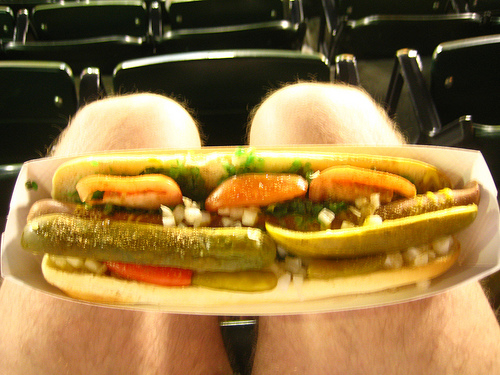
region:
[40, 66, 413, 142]
hairy, pale knees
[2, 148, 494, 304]
hot dog with toppings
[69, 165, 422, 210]
small sliced yellow peppers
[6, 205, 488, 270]
two green pickles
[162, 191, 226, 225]
chopped onion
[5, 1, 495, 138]
black stadium chairs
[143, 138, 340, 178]
green vegetable hot dog topping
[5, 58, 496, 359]
elaborate hot dog resting on a person's legs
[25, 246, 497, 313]
half hot dog bun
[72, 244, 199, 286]
grilled red pepper chunk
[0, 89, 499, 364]
A man has food resting on his legs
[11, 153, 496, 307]
A delicious snack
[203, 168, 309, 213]
A slice of tomato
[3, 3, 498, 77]
Green chairs set up in stadium seating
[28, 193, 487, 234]
A foot long hotdog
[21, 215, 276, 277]
A slice of pickle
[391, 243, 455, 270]
pieces of onion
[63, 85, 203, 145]
The kneecap of a white man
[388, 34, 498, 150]
A green chair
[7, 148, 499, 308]
A hotdog with a lot of trimmings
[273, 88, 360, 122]
Hairy Knee cap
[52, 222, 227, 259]
Pickle slice on hot dog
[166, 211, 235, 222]
White pieces of onion on food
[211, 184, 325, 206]
Tomatoes on hot dog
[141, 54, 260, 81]
Top of black chair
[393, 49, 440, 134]
Shiny black arm rest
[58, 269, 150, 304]
White hot dog bun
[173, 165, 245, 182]
Pieces of green parsley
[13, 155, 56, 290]
White paper box holding hotdog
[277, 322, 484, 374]
Hairy leg under hotdog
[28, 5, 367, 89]
these are some seats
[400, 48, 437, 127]
the legs are made of metal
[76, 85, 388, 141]
these are man's knees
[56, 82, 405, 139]
the feet are hairy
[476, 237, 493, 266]
this is a dish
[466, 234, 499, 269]
the dish is white in color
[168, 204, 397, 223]
these are chopped spices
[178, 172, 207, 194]
the spices are green in color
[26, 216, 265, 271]
this is a pickle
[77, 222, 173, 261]
the pickle is green in color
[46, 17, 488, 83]
these are a few chairs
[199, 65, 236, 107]
the chair is black in color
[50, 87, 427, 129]
the legs are hairy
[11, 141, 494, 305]
this is a lot of food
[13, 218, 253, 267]
the food is green in color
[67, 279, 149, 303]
this is white bread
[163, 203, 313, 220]
these are a lot of spices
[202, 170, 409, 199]
these are some chips